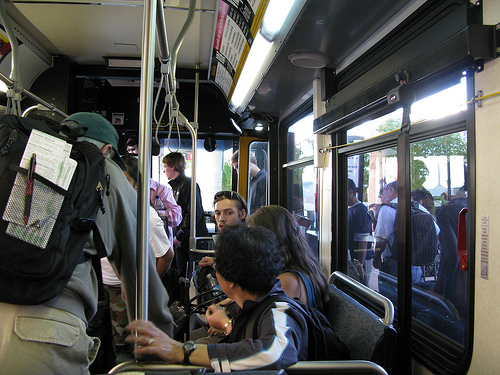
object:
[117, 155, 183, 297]
person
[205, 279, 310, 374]
top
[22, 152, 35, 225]
pen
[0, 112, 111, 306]
backpack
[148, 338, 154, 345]
ring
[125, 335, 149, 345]
finger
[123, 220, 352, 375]
person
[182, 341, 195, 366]
watch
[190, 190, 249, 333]
person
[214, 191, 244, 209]
sunglasses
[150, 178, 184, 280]
part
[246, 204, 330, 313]
part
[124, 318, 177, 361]
hand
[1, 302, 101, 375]
part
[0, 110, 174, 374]
man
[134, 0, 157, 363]
pole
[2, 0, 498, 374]
train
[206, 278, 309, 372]
jacket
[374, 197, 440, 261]
shirt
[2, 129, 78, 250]
paper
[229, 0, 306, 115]
light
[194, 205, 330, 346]
person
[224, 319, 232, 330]
bracelet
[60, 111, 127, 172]
hat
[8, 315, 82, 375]
pocket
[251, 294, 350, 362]
backpack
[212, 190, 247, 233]
head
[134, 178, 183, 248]
sweatshirt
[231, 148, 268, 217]
person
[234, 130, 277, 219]
doorstep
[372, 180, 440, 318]
person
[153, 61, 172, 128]
strap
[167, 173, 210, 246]
jacket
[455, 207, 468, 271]
handle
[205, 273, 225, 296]
bottle